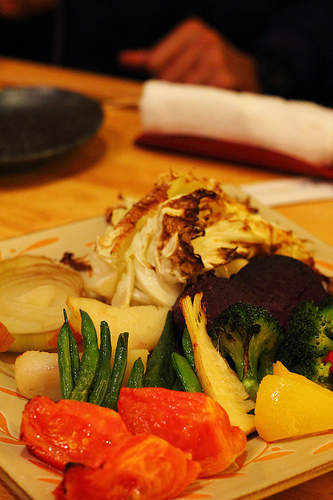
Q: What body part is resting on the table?
A: Hand.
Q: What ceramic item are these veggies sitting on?
A: Plate.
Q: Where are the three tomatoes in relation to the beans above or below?
A: Below.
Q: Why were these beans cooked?
A: To eat.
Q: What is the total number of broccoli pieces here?
A: Two.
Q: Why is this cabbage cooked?
A: To eat.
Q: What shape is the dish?
A: Square.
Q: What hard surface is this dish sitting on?
A: Wood.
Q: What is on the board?
A: Vegetables.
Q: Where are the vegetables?
A: On a board.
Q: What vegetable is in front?
A: Tomatoes.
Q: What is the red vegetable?
A: A tomato.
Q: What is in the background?
A: A black plate.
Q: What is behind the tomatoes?
A: Green beans.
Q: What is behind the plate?
A: Pan.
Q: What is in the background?
A: Hand.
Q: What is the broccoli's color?
A: Green.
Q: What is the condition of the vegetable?
A: Grilled.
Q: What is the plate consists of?
A: Vegetables.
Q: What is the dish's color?
A: Black.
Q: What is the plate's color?
A: White.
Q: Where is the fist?
A: At the top.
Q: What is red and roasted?
A: Tomatoes.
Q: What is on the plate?
A: Roasted vegetables.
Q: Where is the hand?
A: Resting on the table.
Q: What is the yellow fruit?
A: Pineapple.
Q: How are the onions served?
A: Cooked and cut.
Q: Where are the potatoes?
A: On the plate.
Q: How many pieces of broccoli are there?
A: Two.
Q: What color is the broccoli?
A: Green.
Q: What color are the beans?
A: Green.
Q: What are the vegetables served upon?
A: A plate.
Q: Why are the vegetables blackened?
A: They've been cooked.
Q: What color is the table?
A: Brown.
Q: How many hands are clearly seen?
A: One.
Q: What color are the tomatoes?
A: Red.